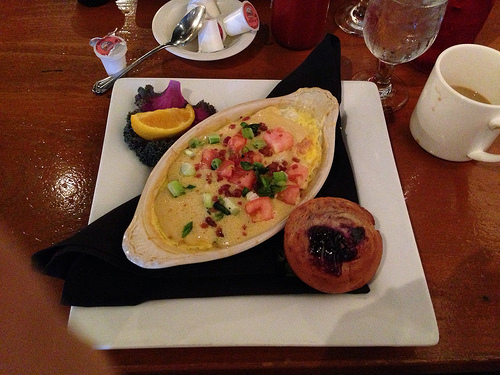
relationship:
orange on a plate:
[131, 106, 195, 138] [70, 76, 439, 345]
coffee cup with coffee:
[409, 43, 500, 162] [454, 85, 492, 106]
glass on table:
[338, 0, 447, 106] [2, 1, 500, 371]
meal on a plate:
[119, 87, 380, 289] [70, 76, 439, 345]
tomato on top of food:
[245, 197, 273, 221] [147, 105, 323, 249]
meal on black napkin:
[119, 87, 380, 289] [34, 34, 367, 306]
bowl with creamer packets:
[150, 0, 259, 60] [185, 2, 258, 55]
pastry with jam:
[287, 200, 382, 293] [309, 220, 365, 277]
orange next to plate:
[131, 106, 195, 138] [70, 76, 439, 345]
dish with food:
[121, 86, 339, 271] [147, 105, 323, 249]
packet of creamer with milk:
[88, 29, 127, 76] [110, 43, 125, 53]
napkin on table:
[88, 2, 210, 96] [2, 1, 500, 371]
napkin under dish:
[34, 34, 367, 306] [121, 86, 339, 271]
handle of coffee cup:
[473, 122, 499, 161] [409, 43, 500, 162]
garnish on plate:
[125, 84, 216, 165] [70, 76, 439, 345]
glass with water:
[338, 0, 447, 106] [364, 4, 444, 63]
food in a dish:
[147, 105, 323, 249] [121, 86, 339, 271]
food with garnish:
[147, 105, 323, 249] [125, 84, 216, 165]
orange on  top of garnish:
[131, 106, 195, 138] [125, 84, 216, 165]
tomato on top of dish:
[245, 197, 273, 221] [121, 86, 339, 271]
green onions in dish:
[172, 128, 274, 239] [121, 86, 339, 271]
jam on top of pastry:
[309, 220, 365, 277] [287, 200, 382, 293]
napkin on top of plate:
[34, 34, 367, 306] [70, 76, 439, 345]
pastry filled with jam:
[287, 200, 382, 293] [309, 220, 365, 277]